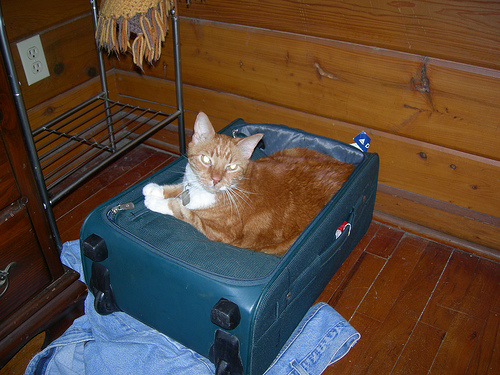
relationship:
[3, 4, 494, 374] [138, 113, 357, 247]
picture has cat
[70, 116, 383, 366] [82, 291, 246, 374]
suitcase has wheels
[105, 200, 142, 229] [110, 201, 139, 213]
zipper has pull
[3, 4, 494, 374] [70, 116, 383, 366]
image has suitcase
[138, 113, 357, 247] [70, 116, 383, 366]
cat in suitcase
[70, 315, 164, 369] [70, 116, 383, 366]
jeans are under suitcase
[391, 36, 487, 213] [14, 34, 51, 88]
wall has oulet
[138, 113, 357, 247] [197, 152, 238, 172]
cat has eyes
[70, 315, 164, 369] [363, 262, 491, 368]
jeans are on floor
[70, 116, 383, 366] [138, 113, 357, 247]
suitcase has cat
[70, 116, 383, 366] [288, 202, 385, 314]
suitcase has handle